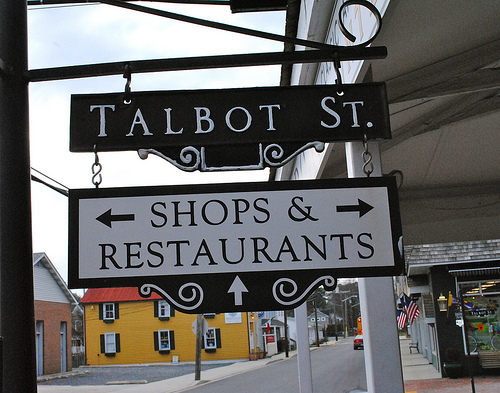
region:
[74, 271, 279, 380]
Bright yellow building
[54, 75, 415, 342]
Two street signs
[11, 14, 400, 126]
Wrought Iron street sign holder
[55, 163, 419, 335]
Black and white street sign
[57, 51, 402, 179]
Black street sign with white writing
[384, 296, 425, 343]
American flags in front of shops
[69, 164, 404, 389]
Sign showing direction of shops and restaurants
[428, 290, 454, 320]
Lantern outside a shop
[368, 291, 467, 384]
Bench on a sidewalk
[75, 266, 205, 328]
Red roof on a yellow building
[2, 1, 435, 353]
Black and white sign hanging on a pole.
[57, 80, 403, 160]
A black sign with the word TALBOT ST.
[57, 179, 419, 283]
A white sign that says SHOPS & RESTAURANTS.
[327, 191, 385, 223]
A black arrow pointing right.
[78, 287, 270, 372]
Yellow building with a red roof.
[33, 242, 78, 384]
Red brick building with a white top.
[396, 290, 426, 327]
An American flag hanging on a storefront wall.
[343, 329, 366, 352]
A car on the road.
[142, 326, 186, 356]
A window with black shutters.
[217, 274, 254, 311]
White arrow pointing upwards.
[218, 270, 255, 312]
arrow pointing up is white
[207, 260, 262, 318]
arrow pointing up is white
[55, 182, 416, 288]
shops and restaurants written on sign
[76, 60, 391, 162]
Talbot St. black and white sign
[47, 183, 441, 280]
Shop and Restaurants sign with left and right arrow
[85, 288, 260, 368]
yellow and orange building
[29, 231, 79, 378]
brick building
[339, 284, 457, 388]
white vinyl post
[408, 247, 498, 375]
various stores on the side of the street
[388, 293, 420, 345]
United States small flag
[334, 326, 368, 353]
car on stop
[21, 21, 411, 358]
black and white signage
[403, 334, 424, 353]
chair on the side of the store